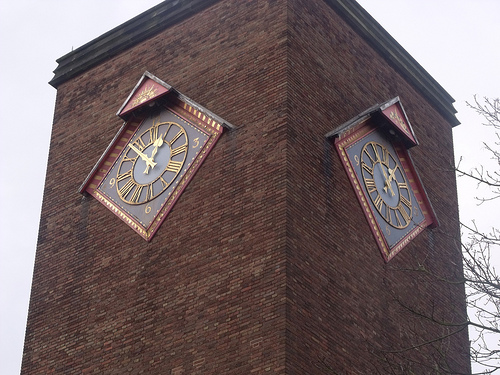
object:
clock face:
[95, 105, 211, 230]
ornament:
[116, 69, 177, 122]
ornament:
[359, 95, 420, 148]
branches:
[439, 155, 500, 185]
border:
[47, 0, 219, 88]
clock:
[95, 107, 210, 230]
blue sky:
[0, 0, 500, 375]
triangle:
[357, 96, 418, 150]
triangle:
[115, 70, 178, 122]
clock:
[342, 124, 425, 252]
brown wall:
[284, 2, 470, 375]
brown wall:
[20, 3, 285, 371]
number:
[145, 203, 152, 213]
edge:
[78, 70, 235, 242]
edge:
[324, 96, 440, 263]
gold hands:
[372, 143, 398, 196]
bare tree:
[377, 94, 500, 375]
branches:
[361, 277, 500, 354]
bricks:
[267, 87, 277, 92]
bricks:
[220, 236, 231, 242]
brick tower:
[18, 0, 472, 372]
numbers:
[354, 154, 359, 165]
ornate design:
[80, 70, 237, 242]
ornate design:
[325, 96, 440, 263]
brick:
[76, 246, 85, 251]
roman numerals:
[160, 176, 168, 188]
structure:
[19, 0, 471, 375]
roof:
[49, 2, 462, 127]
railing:
[49, 0, 462, 127]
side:
[21, 0, 289, 375]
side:
[285, 0, 471, 375]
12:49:
[373, 143, 398, 196]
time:
[346, 127, 425, 251]